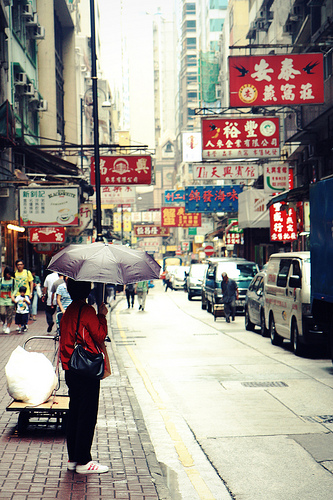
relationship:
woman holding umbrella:
[49, 276, 119, 473] [24, 235, 158, 293]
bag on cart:
[4, 344, 60, 407] [5, 334, 69, 431]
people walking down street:
[122, 274, 151, 314] [116, 282, 330, 490]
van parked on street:
[262, 249, 326, 357] [116, 282, 330, 490]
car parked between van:
[246, 268, 269, 329] [201, 255, 242, 321]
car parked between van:
[246, 268, 269, 329] [264, 253, 316, 351]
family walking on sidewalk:
[1, 257, 34, 335] [0, 287, 169, 499]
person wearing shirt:
[12, 255, 36, 290] [12, 266, 35, 305]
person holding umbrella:
[43, 278, 125, 477] [41, 234, 170, 290]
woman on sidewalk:
[49, 276, 119, 473] [0, 287, 169, 499]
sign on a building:
[223, 51, 325, 109] [247, 27, 331, 358]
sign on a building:
[193, 165, 258, 179] [245, 0, 290, 272]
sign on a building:
[184, 183, 254, 212] [129, 3, 227, 249]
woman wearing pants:
[49, 276, 119, 473] [64, 368, 99, 461]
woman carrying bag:
[49, 276, 119, 473] [65, 332, 110, 386]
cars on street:
[156, 248, 332, 359] [125, 256, 331, 498]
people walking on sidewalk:
[2, 261, 60, 333] [2, 310, 153, 496]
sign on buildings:
[199, 113, 279, 161] [177, 26, 331, 339]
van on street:
[262, 249, 326, 357] [116, 282, 330, 490]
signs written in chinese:
[132, 51, 324, 236] [201, 118, 274, 156]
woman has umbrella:
[49, 276, 119, 473] [38, 236, 172, 282]